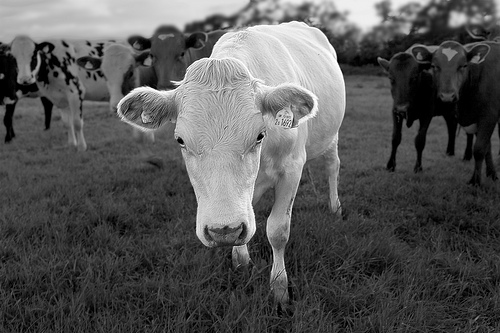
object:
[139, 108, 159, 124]
identification tab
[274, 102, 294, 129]
identification tab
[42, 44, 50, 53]
identification tab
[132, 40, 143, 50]
identification tab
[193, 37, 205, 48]
identification tab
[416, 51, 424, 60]
identification tab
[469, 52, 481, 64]
identification tab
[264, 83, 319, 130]
left ear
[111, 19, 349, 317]
cow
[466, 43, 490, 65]
left ear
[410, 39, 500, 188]
cow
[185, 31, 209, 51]
left ear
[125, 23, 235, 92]
cow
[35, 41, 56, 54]
left ear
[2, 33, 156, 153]
cow